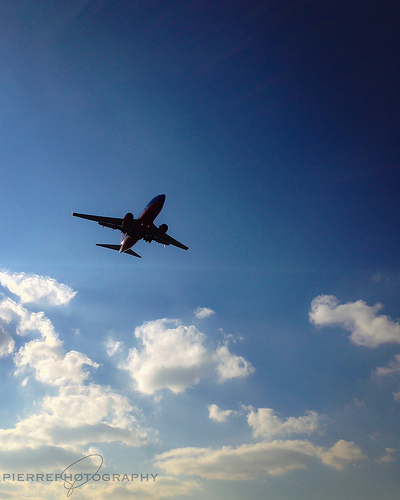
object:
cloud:
[308, 294, 397, 351]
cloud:
[107, 319, 252, 394]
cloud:
[1, 270, 143, 478]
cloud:
[5, 437, 365, 499]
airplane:
[73, 194, 190, 257]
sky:
[3, 3, 397, 498]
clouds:
[0, 269, 399, 499]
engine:
[121, 213, 133, 230]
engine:
[154, 224, 167, 242]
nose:
[139, 193, 165, 225]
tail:
[96, 236, 141, 259]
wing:
[146, 225, 190, 250]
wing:
[73, 211, 137, 234]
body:
[121, 193, 166, 252]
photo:
[0, 0, 399, 499]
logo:
[3, 458, 159, 495]